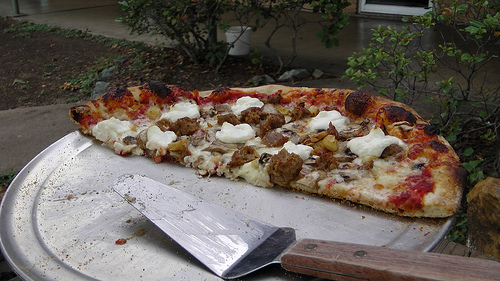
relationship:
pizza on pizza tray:
[75, 50, 464, 218] [13, 121, 451, 268]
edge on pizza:
[345, 88, 418, 126] [75, 50, 464, 218]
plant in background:
[357, 1, 498, 240] [327, 32, 471, 107]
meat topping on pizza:
[215, 113, 240, 125] [75, 50, 464, 218]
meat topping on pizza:
[379, 143, 404, 158] [75, 50, 464, 218]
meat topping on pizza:
[171, 115, 199, 135] [75, 50, 464, 218]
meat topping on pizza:
[259, 113, 285, 130] [75, 50, 464, 218]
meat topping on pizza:
[266, 148, 303, 187] [75, 50, 464, 218]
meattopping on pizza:
[264, 127, 293, 146] [75, 50, 464, 218]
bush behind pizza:
[345, 4, 497, 244] [34, 49, 289, 273]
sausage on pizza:
[260, 135, 318, 194] [75, 50, 464, 218]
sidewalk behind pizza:
[4, 102, 74, 184] [75, 50, 464, 218]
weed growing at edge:
[25, 17, 132, 103] [26, 18, 161, 52]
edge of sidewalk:
[26, 18, 161, 52] [22, 5, 495, 115]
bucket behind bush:
[220, 26, 255, 54] [126, 6, 346, 67]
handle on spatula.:
[285, 236, 499, 279] [99, 142, 231, 279]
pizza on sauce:
[75, 50, 464, 218] [391, 167, 435, 210]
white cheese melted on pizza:
[149, 105, 399, 165] [75, 50, 464, 218]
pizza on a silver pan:
[75, 50, 464, 218] [0, 132, 455, 279]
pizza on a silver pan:
[75, 50, 487, 230] [0, 132, 455, 279]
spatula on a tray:
[108, 170, 497, 278] [1, 128, 453, 279]